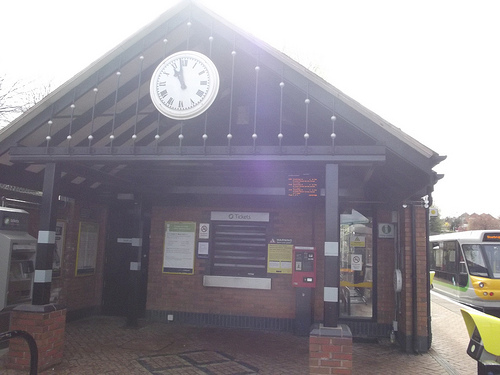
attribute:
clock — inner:
[143, 45, 219, 123]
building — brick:
[1, 156, 431, 353]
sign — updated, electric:
[260, 163, 331, 221]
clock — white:
[149, 49, 219, 124]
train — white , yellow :
[435, 231, 492, 295]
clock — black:
[148, 49, 221, 119]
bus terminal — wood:
[1, 4, 431, 354]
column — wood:
[320, 168, 342, 328]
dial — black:
[169, 56, 189, 89]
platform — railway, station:
[19, 7, 494, 372]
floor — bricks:
[0, 291, 497, 373]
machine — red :
[291, 245, 318, 287]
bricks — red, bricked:
[302, 322, 359, 372]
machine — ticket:
[290, 244, 317, 336]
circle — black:
[175, 78, 189, 96]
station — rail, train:
[6, 7, 498, 372]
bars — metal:
[45, 19, 345, 156]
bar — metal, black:
[320, 164, 340, 324]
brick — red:
[14, 309, 66, 362]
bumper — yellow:
[470, 279, 499, 300]